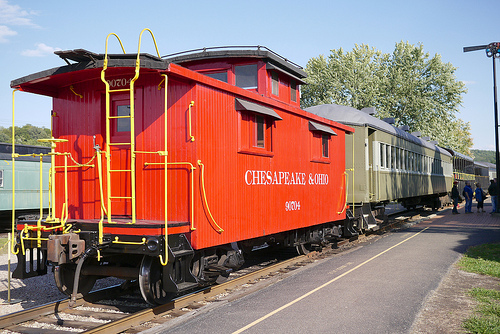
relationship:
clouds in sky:
[222, 14, 254, 36] [0, 3, 498, 150]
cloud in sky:
[0, 18, 18, 52] [0, 3, 498, 150]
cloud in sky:
[1, 6, 42, 28] [0, 3, 498, 150]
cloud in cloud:
[17, 36, 59, 59] [0, 18, 18, 52]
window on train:
[253, 111, 265, 151] [12, 47, 471, 307]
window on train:
[232, 65, 260, 93] [34, 35, 365, 295]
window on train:
[114, 104, 129, 131] [6, 27, 496, 308]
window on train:
[232, 65, 260, 93] [6, 27, 496, 308]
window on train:
[269, 74, 277, 96] [6, 27, 496, 308]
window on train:
[290, 83, 296, 101] [6, 27, 496, 308]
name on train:
[228, 160, 341, 199] [6, 27, 496, 308]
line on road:
[230, 221, 430, 331] [146, 196, 498, 331]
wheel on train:
[122, 241, 184, 312] [6, 27, 496, 308]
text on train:
[240, 164, 333, 189] [6, 27, 496, 308]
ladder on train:
[96, 25, 159, 213] [6, 27, 496, 308]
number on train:
[283, 199, 301, 211] [6, 27, 496, 308]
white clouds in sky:
[0, 0, 48, 49] [168, 10, 348, 34]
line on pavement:
[230, 221, 430, 331] [135, 220, 478, 330]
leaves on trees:
[316, 47, 402, 122] [321, 62, 445, 127]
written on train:
[242, 167, 308, 187] [6, 27, 496, 308]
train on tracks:
[6, 27, 496, 308] [0, 200, 480, 332]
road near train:
[162, 203, 485, 323] [56, 27, 358, 252]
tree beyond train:
[285, 42, 474, 159] [24, 27, 496, 269]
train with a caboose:
[6, 27, 496, 308] [8, 32, 354, 312]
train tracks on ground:
[0, 200, 456, 332] [15, 200, 485, 325]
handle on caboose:
[164, 100, 217, 149] [0, 37, 373, 304]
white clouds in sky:
[0, 0, 48, 49] [0, 3, 498, 150]